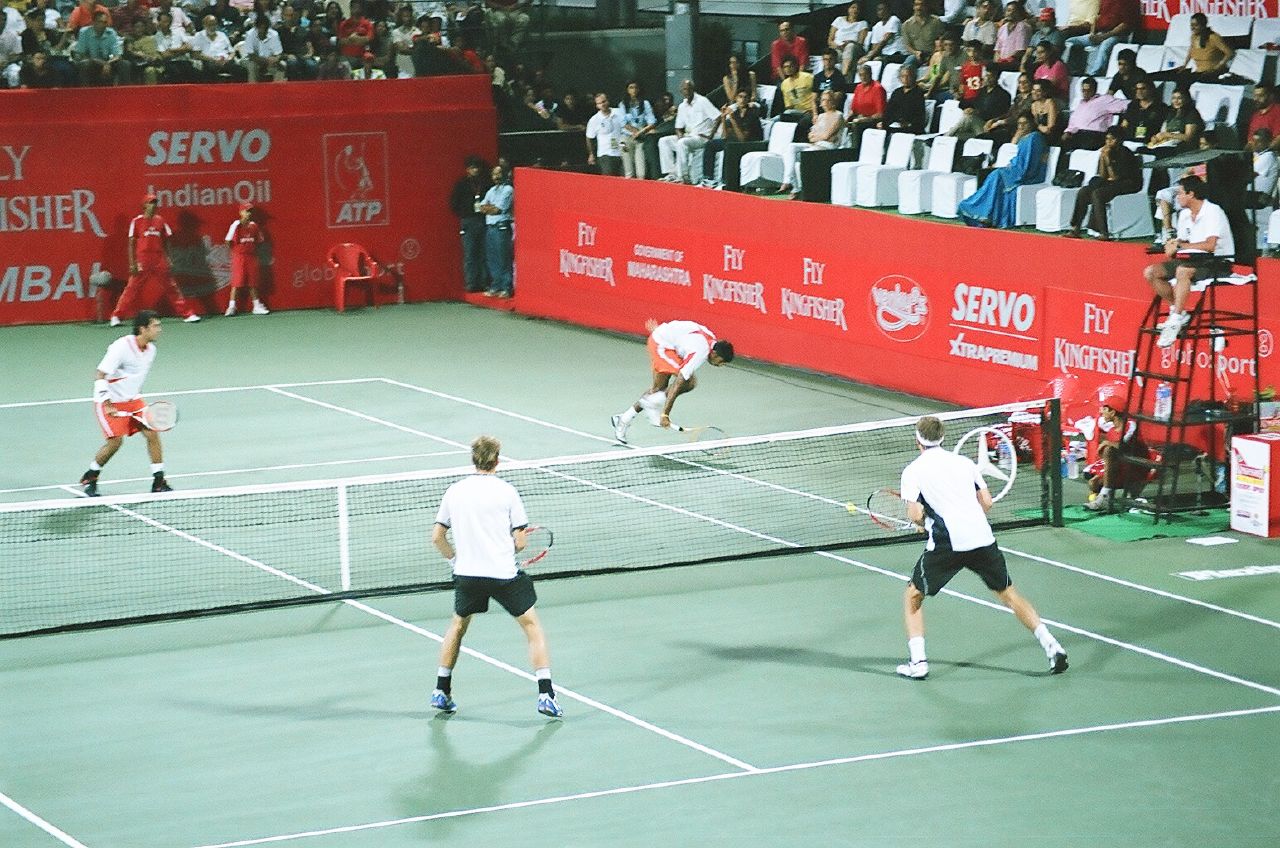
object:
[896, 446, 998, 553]
shirt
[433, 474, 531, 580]
top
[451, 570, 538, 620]
short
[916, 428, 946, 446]
headband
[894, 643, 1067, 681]
shoes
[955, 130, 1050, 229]
dress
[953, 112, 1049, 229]
woman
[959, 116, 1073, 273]
chair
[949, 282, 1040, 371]
letters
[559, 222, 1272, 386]
sign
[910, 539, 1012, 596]
shorts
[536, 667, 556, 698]
socks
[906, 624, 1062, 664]
socks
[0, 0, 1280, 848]
scene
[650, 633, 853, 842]
court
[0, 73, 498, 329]
wall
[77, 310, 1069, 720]
men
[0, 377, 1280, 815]
lines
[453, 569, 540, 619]
shorts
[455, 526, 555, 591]
racket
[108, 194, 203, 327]
man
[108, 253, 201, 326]
legs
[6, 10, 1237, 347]
people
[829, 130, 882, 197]
chair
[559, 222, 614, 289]
logo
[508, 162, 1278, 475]
banner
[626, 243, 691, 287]
logo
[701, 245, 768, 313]
logo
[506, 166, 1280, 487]
banner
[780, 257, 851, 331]
logo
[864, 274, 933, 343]
logo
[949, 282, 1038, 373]
logo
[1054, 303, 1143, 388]
logo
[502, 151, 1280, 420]
banner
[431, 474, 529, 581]
shirt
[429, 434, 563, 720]
man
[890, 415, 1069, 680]
man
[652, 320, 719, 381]
shirt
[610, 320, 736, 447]
man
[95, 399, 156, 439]
shorts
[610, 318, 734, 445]
tennis player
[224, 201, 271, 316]
ball boy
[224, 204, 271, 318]
clothing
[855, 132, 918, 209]
chair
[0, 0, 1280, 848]
stadium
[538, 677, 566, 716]
shoe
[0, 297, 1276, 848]
tennis court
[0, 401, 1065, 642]
net